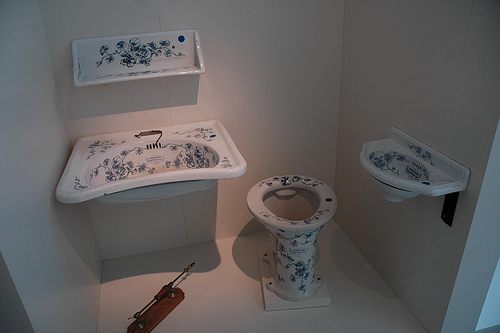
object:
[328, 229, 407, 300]
shadow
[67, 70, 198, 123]
shadow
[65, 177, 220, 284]
shadow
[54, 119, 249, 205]
sink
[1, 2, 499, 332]
bathroom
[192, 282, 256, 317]
white flooring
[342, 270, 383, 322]
flooring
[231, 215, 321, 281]
shadow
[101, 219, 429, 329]
floor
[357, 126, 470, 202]
sink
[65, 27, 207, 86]
shelf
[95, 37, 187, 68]
flowers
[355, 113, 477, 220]
sink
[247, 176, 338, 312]
toilet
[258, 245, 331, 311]
base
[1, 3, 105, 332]
wall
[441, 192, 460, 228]
bracket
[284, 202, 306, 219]
stain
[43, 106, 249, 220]
sink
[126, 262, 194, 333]
object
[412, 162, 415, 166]
drain holes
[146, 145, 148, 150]
drain holes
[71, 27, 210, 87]
picture